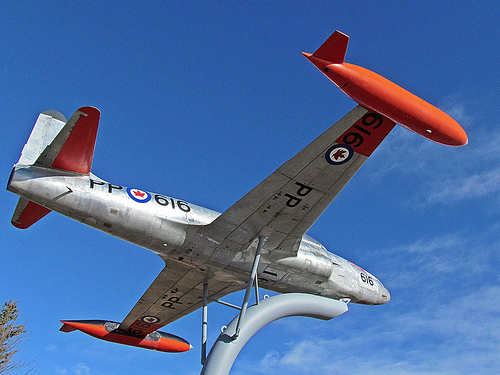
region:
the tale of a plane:
[6, 103, 103, 237]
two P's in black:
[288, 171, 315, 221]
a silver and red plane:
[8, 21, 469, 351]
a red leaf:
[328, 145, 350, 163]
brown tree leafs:
[0, 293, 32, 372]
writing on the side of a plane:
[86, 170, 191, 211]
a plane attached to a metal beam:
[13, 42, 384, 362]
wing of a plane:
[201, 38, 471, 255]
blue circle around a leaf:
[126, 182, 152, 204]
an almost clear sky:
[12, 30, 497, 361]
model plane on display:
[0, 72, 439, 368]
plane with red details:
[8, 43, 453, 353]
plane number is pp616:
[2, 91, 481, 363]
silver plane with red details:
[1, 159, 485, 367]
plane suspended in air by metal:
[0, 113, 427, 370]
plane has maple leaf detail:
[4, 160, 463, 361]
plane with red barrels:
[24, 32, 426, 369]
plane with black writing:
[1, 46, 481, 366]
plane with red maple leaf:
[8, 34, 488, 358]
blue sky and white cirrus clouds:
[417, 209, 474, 311]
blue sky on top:
[149, 35, 221, 100]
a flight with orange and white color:
[3, 35, 473, 370]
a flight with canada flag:
[124, 176, 157, 208]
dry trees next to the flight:
[1, 282, 53, 370]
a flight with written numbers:
[281, 110, 384, 212]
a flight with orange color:
[288, 45, 475, 178]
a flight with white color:
[90, 187, 126, 232]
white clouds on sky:
[432, 215, 475, 278]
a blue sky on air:
[178, 74, 260, 121]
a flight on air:
[16, 52, 498, 362]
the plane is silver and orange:
[0, 6, 472, 371]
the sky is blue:
[0, 0, 495, 310]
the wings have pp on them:
[105, 36, 465, 367]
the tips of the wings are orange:
[42, 275, 199, 360]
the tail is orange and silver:
[10, 92, 127, 252]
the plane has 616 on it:
[145, 175, 201, 247]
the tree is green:
[0, 295, 41, 372]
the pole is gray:
[183, 282, 368, 374]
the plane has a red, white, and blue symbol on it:
[88, 168, 184, 222]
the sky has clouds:
[251, 29, 487, 374]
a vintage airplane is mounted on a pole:
[0, 44, 481, 366]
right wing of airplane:
[241, 56, 391, 251]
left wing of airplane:
[126, 245, 221, 351]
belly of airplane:
[136, 221, 311, 282]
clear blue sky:
[8, 7, 300, 89]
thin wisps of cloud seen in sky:
[397, 194, 497, 372]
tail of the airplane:
[7, 95, 99, 230]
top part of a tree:
[1, 291, 39, 370]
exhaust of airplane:
[5, 154, 27, 209]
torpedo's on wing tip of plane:
[290, 20, 482, 155]